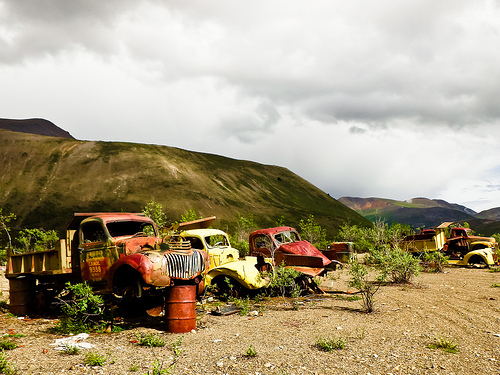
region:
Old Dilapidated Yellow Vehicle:
[181, 227, 269, 295]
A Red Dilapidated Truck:
[9, 206, 209, 336]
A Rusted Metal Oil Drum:
[160, 277, 205, 332]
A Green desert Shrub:
[348, 242, 380, 315]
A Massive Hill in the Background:
[1, 116, 378, 231]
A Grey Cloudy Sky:
[2, 0, 476, 110]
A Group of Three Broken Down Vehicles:
[0, 192, 346, 313]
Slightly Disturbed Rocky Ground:
[393, 291, 498, 331]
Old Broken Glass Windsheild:
[270, 230, 306, 246]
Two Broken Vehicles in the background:
[386, 220, 498, 264]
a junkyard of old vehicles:
[8, 178, 494, 302]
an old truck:
[3, 205, 215, 342]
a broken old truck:
[397, 205, 499, 281]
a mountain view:
[5, 118, 492, 208]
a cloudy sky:
[198, 57, 486, 146]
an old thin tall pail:
[161, 275, 205, 346]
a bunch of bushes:
[339, 234, 414, 319]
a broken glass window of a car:
[253, 227, 300, 249]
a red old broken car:
[243, 220, 340, 290]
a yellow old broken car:
[186, 220, 261, 310]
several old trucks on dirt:
[23, 17, 476, 373]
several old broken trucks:
[53, 200, 339, 333]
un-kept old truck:
[35, 185, 172, 322]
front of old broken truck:
[78, 196, 200, 303]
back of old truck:
[8, 222, 78, 313]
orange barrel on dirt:
[156, 280, 200, 325]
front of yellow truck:
[175, 211, 249, 316]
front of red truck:
[258, 197, 320, 272]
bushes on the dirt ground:
[383, 321, 455, 369]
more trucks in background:
[413, 220, 475, 277]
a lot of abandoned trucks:
[27, 217, 498, 332]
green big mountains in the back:
[7, 137, 464, 238]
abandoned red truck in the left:
[0, 201, 208, 323]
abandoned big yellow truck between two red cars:
[172, 227, 276, 294]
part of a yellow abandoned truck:
[401, 224, 492, 271]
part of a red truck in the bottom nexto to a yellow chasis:
[426, 225, 496, 252]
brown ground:
[28, 257, 498, 373]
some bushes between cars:
[76, 218, 413, 330]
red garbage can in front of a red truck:
[166, 283, 194, 336]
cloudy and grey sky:
[4, 1, 499, 192]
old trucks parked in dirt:
[25, 203, 335, 328]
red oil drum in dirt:
[164, 278, 210, 343]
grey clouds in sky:
[110, 17, 417, 163]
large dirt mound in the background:
[21, 125, 373, 227]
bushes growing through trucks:
[148, 203, 375, 262]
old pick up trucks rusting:
[33, 209, 368, 312]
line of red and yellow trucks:
[28, 211, 388, 309]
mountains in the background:
[335, 189, 495, 234]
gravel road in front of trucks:
[226, 293, 470, 365]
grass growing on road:
[243, 324, 468, 361]